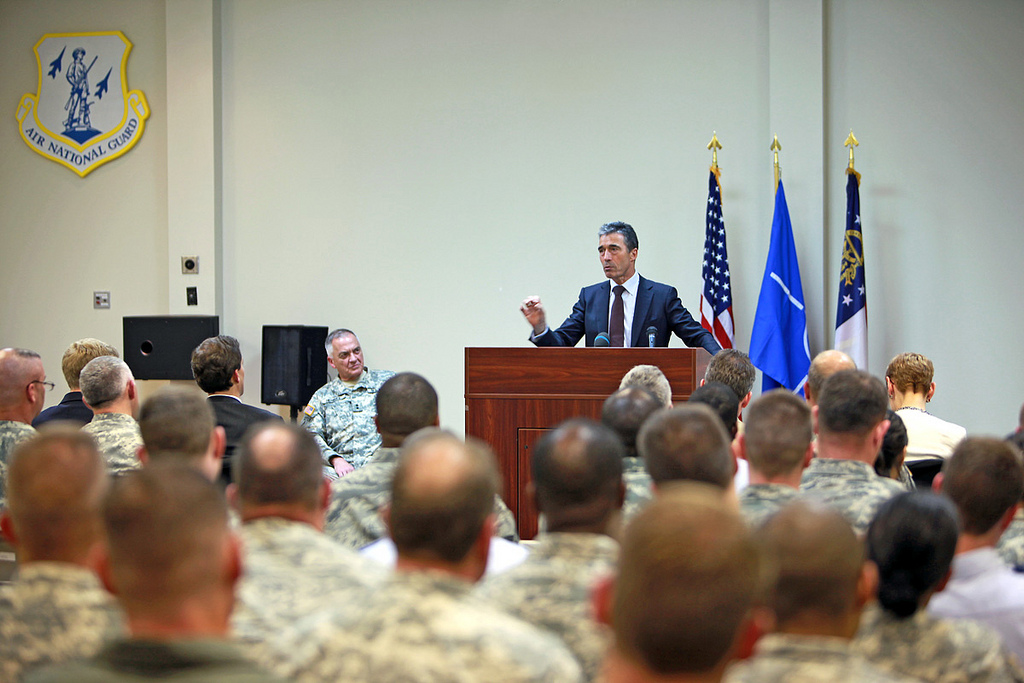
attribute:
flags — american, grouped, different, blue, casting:
[696, 135, 893, 390]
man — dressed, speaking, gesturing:
[487, 212, 725, 353]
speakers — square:
[114, 306, 338, 416]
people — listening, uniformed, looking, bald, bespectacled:
[28, 333, 1015, 653]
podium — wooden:
[455, 335, 750, 535]